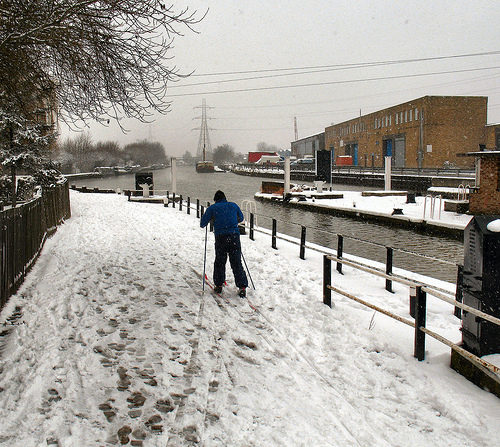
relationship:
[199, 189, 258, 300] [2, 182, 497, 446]
skier on sidewalk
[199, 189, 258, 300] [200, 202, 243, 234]
skier wearing jacket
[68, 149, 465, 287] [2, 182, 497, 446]
canal beside sidewalk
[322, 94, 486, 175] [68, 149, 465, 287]
building by canal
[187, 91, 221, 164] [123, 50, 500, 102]
tower for power wires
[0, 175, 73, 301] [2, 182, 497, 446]
fence along sidewalk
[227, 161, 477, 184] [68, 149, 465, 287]
railing along canal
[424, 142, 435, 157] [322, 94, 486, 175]
sign on building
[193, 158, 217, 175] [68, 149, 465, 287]
barge on canal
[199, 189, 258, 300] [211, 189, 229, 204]
skier wearing cap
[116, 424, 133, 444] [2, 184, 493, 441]
footprint in snow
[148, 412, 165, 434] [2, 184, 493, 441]
footprint in snow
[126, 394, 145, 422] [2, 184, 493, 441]
footprint in snow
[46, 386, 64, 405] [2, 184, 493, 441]
footprint in snow